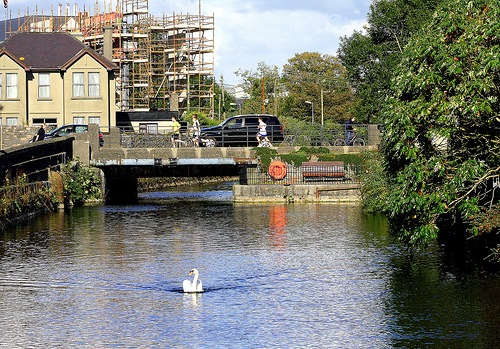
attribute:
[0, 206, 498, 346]
water — calm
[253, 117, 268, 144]
person — running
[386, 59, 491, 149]
leaves — green 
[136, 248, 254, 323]
swan — swimming